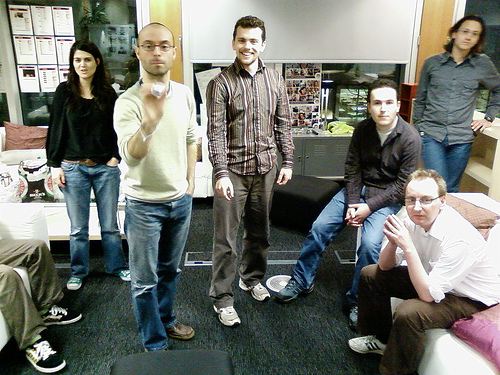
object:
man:
[275, 78, 422, 326]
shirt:
[379, 205, 499, 309]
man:
[112, 21, 200, 352]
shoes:
[144, 320, 195, 354]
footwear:
[201, 277, 272, 328]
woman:
[43, 38, 134, 292]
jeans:
[123, 193, 193, 352]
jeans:
[62, 161, 127, 278]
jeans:
[292, 182, 407, 305]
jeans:
[420, 127, 472, 193]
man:
[412, 14, 499, 193]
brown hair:
[440, 14, 488, 57]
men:
[111, 15, 499, 375]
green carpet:
[0, 188, 419, 375]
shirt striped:
[206, 55, 296, 183]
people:
[0, 0, 500, 375]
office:
[0, 0, 500, 375]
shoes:
[213, 302, 242, 327]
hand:
[383, 214, 415, 251]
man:
[346, 169, 500, 375]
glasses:
[404, 195, 441, 206]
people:
[42, 16, 499, 375]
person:
[112, 21, 196, 353]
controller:
[151, 81, 166, 97]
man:
[203, 15, 294, 328]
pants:
[207, 157, 279, 310]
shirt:
[206, 56, 296, 184]